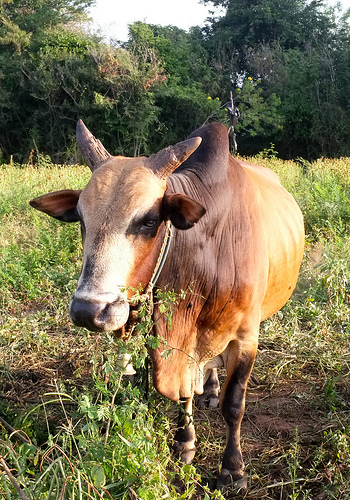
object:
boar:
[30, 105, 312, 498]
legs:
[220, 354, 255, 498]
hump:
[177, 127, 265, 176]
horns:
[149, 129, 202, 178]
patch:
[261, 387, 309, 449]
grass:
[302, 172, 339, 219]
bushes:
[54, 394, 150, 470]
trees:
[305, 25, 349, 165]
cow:
[23, 123, 307, 469]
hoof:
[227, 468, 260, 497]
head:
[30, 142, 208, 337]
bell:
[111, 348, 149, 386]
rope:
[140, 213, 170, 287]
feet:
[168, 434, 197, 470]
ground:
[260, 328, 347, 457]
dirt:
[261, 402, 290, 424]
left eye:
[139, 215, 157, 236]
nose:
[71, 293, 107, 328]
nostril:
[93, 301, 115, 326]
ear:
[154, 196, 210, 239]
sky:
[111, 8, 137, 26]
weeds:
[1, 164, 9, 207]